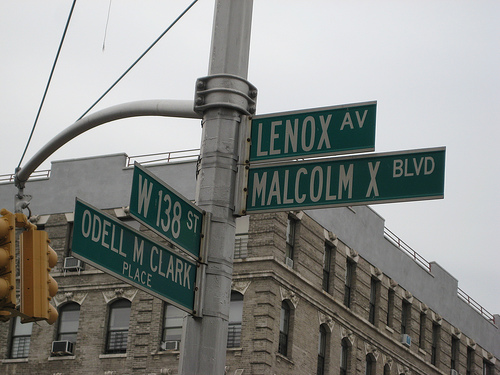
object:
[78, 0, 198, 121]
wire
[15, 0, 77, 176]
wire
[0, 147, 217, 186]
fence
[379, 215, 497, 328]
fence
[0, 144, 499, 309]
roof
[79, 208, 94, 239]
white letters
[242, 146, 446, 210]
signs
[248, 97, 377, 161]
sign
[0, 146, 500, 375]
building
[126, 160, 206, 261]
street sign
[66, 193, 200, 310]
street sign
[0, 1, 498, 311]
sky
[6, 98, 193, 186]
arm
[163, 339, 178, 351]
conditioner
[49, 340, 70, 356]
conditioner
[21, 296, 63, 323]
signal light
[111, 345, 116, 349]
bars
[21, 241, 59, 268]
light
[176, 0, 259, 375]
post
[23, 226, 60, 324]
signal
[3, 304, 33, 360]
window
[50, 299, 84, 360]
window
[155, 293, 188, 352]
window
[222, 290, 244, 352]
window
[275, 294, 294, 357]
window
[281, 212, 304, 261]
window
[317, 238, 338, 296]
window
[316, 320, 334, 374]
window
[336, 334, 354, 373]
window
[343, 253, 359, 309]
window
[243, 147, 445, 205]
writing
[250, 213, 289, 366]
parapets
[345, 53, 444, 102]
distance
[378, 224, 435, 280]
railing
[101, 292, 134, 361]
window